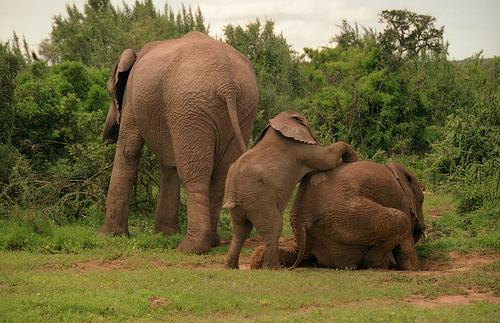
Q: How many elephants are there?
A: Three.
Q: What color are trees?
A: Green.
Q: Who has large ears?
A: The elephants.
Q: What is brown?
A: Dirt.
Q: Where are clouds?
A: In the sky.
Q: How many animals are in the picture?
A: 3.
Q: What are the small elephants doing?
A: Playing.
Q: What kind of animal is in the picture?
A: Elephants.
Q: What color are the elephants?
A: Brown.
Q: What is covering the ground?
A: Grass.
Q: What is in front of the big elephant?
A: Trees.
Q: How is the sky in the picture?
A: Cloudy.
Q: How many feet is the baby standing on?
A: 2.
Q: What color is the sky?
A: Gray.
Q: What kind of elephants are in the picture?
A: African elephants.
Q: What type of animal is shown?
A: Elephant.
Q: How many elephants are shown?
A: 3.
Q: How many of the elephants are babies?
A: 1.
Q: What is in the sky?
A: Clouds.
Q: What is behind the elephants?
A: Trees.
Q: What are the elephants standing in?
A: Grass.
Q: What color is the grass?
A: Green.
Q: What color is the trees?
A: Green.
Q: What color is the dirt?
A: Brown.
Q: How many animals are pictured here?
A: Three.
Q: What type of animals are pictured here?
A: Elephants.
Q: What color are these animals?
A: Brown.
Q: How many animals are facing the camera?
A: Zero.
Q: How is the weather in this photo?
A: Overcast.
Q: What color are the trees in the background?
A: Green.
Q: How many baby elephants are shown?
A: Two.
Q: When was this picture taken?
A: Afternoon.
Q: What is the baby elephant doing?
A: Leaning on the other elephant.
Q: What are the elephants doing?
A: Playing.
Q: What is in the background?
A: Trees.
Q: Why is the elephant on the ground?
A: Resting.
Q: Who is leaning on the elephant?
A: A baby elephant.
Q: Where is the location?
A: Safari.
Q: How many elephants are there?
A: Three.